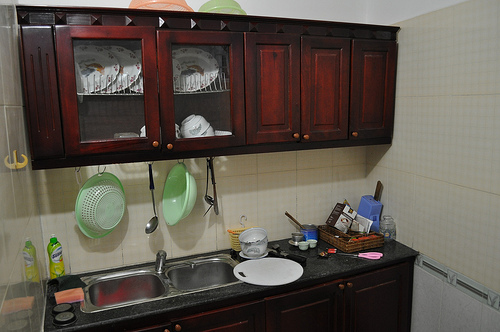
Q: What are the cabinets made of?
A: Reddish black wood.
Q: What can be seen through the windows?
A: Dishes and cups.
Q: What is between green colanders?
A: A hanging ladle.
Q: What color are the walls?
A: White.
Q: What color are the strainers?
A: Green.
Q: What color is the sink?
A: Gray.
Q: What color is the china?
A: White.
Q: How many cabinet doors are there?
A: 5.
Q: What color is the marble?
A: Gray.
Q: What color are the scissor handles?
A: Pink.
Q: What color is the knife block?
A: Blue.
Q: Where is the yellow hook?
A: On the wall.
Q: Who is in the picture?
A: No one.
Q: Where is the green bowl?
A: Hanging underneath the cabinets.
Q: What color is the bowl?
A: Green.